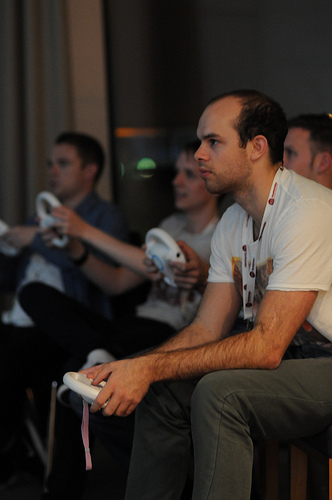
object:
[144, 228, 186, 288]
controller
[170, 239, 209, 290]
hand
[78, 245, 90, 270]
black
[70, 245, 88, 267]
worn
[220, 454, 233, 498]
gray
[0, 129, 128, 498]
man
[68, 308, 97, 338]
black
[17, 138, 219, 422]
man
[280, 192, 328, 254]
white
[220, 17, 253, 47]
gray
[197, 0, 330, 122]
wall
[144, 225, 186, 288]
wii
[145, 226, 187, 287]
wheel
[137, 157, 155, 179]
light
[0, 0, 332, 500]
background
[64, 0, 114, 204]
thick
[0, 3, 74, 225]
curtain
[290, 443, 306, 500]
legs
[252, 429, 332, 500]
chair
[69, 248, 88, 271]
band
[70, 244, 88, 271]
wrist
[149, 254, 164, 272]
circle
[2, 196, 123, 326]
shirt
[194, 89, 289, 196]
head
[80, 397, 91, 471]
cord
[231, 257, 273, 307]
tag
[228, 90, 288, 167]
hair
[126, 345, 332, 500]
jeans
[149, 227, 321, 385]
arm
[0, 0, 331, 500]
playin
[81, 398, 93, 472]
wristband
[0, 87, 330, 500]
four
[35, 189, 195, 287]
racing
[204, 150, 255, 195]
shave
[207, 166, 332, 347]
shirt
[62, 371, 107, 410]
game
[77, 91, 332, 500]
person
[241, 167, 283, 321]
lanyard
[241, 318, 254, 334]
ticket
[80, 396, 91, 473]
string